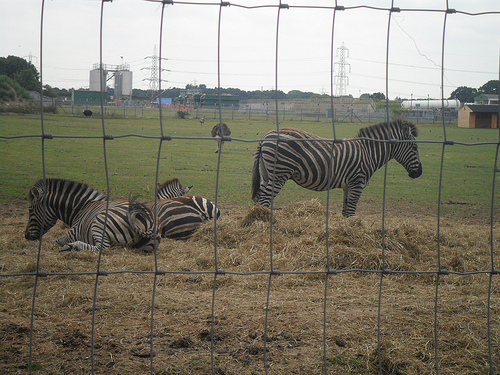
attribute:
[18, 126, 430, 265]
zebras — bunch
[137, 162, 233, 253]
zebra — bunch  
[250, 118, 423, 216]
zebra — bunch  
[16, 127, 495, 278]
zebras — bunch  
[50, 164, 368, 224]
zebras — bunch  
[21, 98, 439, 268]
zebras. — bunch  